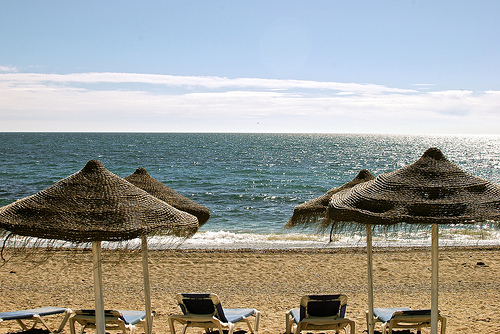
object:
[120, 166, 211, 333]
umbrella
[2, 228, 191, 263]
fringes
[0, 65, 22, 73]
clouds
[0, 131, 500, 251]
water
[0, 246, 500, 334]
ashore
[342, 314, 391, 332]
shade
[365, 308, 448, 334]
chair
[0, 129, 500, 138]
horizon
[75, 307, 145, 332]
chair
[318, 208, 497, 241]
fringe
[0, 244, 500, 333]
sand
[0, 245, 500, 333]
ground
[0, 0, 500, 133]
sky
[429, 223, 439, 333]
poles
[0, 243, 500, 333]
beach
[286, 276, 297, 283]
footprints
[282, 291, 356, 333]
lounger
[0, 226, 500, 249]
waves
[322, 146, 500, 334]
umbrella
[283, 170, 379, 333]
umbrella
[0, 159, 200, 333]
umbrella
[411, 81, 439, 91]
clouds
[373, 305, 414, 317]
sit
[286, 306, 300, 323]
sit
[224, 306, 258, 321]
sit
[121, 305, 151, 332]
sit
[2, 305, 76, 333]
chair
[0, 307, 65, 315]
sit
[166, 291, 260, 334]
lounge chair